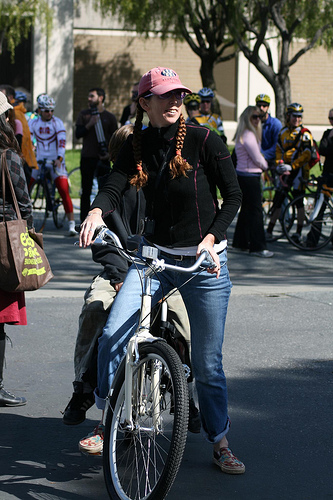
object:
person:
[77, 65, 246, 475]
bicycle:
[76, 226, 217, 499]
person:
[62, 125, 202, 436]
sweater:
[235, 129, 269, 174]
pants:
[28, 165, 74, 215]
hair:
[128, 93, 193, 193]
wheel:
[102, 336, 191, 500]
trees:
[0, 0, 54, 65]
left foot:
[213, 446, 246, 474]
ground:
[0, 147, 332, 500]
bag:
[0, 147, 55, 294]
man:
[27, 92, 79, 234]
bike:
[28, 157, 67, 233]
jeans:
[93, 238, 233, 444]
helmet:
[35, 90, 58, 112]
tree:
[92, 0, 241, 125]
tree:
[219, 2, 332, 125]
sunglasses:
[40, 107, 54, 113]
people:
[231, 104, 274, 258]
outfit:
[27, 117, 78, 236]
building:
[33, 0, 333, 146]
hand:
[196, 235, 221, 279]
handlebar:
[75, 222, 217, 275]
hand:
[79, 208, 105, 249]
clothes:
[75, 108, 119, 159]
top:
[233, 129, 269, 175]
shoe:
[78, 421, 104, 458]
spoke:
[144, 436, 151, 496]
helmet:
[285, 102, 304, 117]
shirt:
[88, 119, 244, 249]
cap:
[138, 65, 194, 99]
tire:
[102, 338, 189, 500]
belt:
[160, 250, 196, 261]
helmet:
[183, 92, 201, 110]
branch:
[221, 0, 254, 61]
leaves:
[3, 0, 9, 10]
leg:
[50, 163, 75, 223]